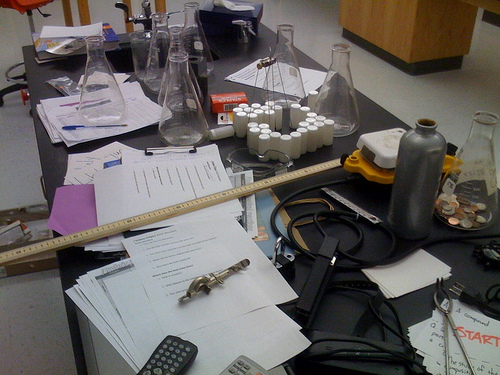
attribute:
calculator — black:
[134, 332, 198, 374]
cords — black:
[273, 182, 435, 367]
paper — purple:
[25, 159, 134, 265]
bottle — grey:
[382, 115, 449, 242]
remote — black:
[138, 331, 203, 373]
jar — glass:
[314, 35, 357, 145]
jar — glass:
[435, 102, 498, 231]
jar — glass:
[385, 117, 443, 237]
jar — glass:
[157, 52, 210, 147]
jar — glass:
[74, 31, 131, 123]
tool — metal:
[177, 256, 251, 305]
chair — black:
[0, 0, 50, 117]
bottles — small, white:
[224, 92, 346, 160]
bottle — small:
[207, 124, 234, 139]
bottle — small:
[307, 89, 317, 109]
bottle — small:
[322, 119, 332, 146]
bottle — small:
[257, 134, 270, 160]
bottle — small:
[280, 133, 289, 161]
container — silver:
[387, 113, 444, 239]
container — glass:
[442, 104, 497, 237]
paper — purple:
[46, 148, 126, 257]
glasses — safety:
[225, 147, 292, 177]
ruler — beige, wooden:
[9, 159, 346, 270]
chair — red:
[2, 0, 64, 110]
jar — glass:
[435, 113, 493, 230]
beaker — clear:
[138, 17, 223, 165]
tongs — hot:
[433, 277, 477, 374]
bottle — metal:
[381, 114, 459, 248]